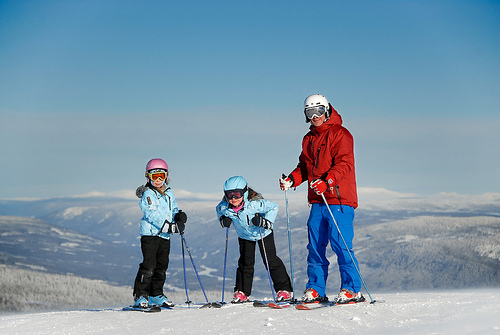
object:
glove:
[280, 173, 327, 195]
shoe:
[134, 296, 161, 308]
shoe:
[154, 294, 174, 307]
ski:
[123, 306, 171, 312]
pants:
[233, 229, 292, 296]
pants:
[132, 236, 168, 301]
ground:
[0, 288, 497, 335]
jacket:
[136, 183, 178, 241]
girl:
[132, 158, 186, 307]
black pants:
[132, 236, 169, 301]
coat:
[287, 105, 357, 209]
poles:
[178, 210, 209, 309]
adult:
[132, 94, 360, 309]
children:
[132, 158, 293, 308]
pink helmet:
[143, 159, 169, 174]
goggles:
[306, 106, 324, 119]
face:
[310, 114, 325, 126]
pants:
[306, 203, 362, 293]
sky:
[0, 0, 500, 200]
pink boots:
[226, 282, 296, 306]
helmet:
[304, 94, 329, 124]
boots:
[134, 296, 175, 310]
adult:
[277, 95, 357, 304]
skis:
[255, 299, 366, 310]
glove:
[252, 216, 272, 229]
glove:
[220, 215, 233, 228]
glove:
[174, 210, 187, 223]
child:
[215, 177, 293, 303]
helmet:
[224, 176, 248, 203]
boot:
[277, 289, 294, 302]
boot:
[231, 291, 247, 303]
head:
[145, 158, 169, 188]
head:
[304, 93, 330, 126]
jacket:
[215, 194, 278, 242]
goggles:
[145, 172, 167, 181]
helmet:
[145, 158, 168, 183]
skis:
[200, 301, 290, 310]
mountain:
[0, 188, 500, 335]